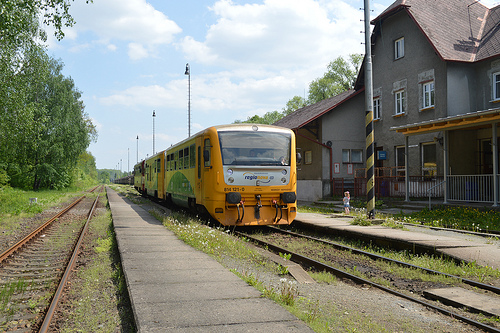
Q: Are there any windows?
A: Yes, there is a window.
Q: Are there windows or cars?
A: Yes, there is a window.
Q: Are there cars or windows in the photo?
A: Yes, there is a window.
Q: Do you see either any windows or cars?
A: Yes, there is a window.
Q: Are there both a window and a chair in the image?
A: No, there is a window but no chairs.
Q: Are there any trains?
A: Yes, there is a train.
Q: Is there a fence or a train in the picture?
A: Yes, there is a train.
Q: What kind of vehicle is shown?
A: The vehicle is a train.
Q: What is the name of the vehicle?
A: The vehicle is a train.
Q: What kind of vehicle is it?
A: The vehicle is a train.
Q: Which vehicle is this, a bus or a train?
A: This is a train.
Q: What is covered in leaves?
A: The tree is covered in leaves.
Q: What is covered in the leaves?
A: The tree is covered in leaves.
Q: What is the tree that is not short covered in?
A: The tree is covered in leaves.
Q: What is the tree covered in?
A: The tree is covered in leaves.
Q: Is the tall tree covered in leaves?
A: Yes, the tree is covered in leaves.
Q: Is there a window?
A: Yes, there is a window.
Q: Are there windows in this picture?
A: Yes, there is a window.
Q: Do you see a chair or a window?
A: Yes, there is a window.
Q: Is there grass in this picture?
A: Yes, there is grass.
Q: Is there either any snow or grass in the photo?
A: Yes, there is grass.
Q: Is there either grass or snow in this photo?
A: Yes, there is grass.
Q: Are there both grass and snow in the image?
A: No, there is grass but no snow.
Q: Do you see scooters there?
A: No, there are no scooters.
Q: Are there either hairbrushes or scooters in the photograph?
A: No, there are no scooters or hairbrushes.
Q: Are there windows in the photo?
A: Yes, there is a window.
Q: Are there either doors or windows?
A: Yes, there is a window.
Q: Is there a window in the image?
A: Yes, there is a window.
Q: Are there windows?
A: Yes, there is a window.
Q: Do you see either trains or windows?
A: Yes, there is a window.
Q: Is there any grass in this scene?
A: Yes, there is grass.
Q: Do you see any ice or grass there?
A: Yes, there is grass.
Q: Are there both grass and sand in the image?
A: No, there is grass but no sand.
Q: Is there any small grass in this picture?
A: Yes, there is small grass.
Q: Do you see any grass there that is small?
A: Yes, there is grass that is small.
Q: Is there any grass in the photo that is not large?
A: Yes, there is small grass.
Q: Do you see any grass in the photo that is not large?
A: Yes, there is small grass.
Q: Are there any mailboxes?
A: No, there are no mailboxes.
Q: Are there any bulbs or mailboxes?
A: No, there are no mailboxes or bulbs.